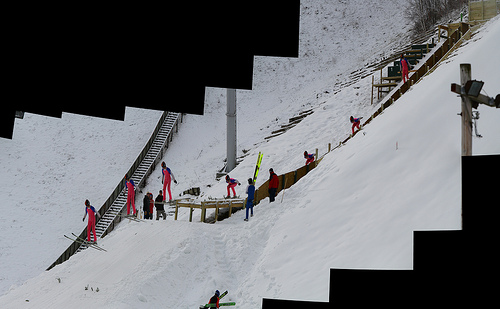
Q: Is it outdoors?
A: Yes, it is outdoors.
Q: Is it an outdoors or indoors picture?
A: It is outdoors.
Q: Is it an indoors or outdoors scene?
A: It is outdoors.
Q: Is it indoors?
A: No, it is outdoors.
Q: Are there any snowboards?
A: No, there are no snowboards.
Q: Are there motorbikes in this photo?
A: No, there are no motorbikes.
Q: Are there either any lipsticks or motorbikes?
A: No, there are no motorbikes or lipsticks.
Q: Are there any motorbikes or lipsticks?
A: No, there are no motorbikes or lipsticks.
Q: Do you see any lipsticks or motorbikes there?
A: No, there are no motorbikes or lipsticks.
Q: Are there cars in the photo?
A: No, there are no cars.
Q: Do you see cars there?
A: No, there are no cars.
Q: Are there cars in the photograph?
A: No, there are no cars.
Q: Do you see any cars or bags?
A: No, there are no cars or bags.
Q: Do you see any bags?
A: No, there are no bags.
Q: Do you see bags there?
A: No, there are no bags.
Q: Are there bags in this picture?
A: No, there are no bags.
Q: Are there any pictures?
A: No, there are no pictures.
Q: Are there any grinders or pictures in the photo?
A: No, there are no pictures or grinders.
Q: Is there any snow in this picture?
A: Yes, there is snow.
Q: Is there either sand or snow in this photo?
A: Yes, there is snow.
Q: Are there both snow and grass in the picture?
A: No, there is snow but no grass.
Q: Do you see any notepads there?
A: No, there are no notepads.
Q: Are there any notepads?
A: No, there are no notepads.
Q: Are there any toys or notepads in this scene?
A: No, there are no notepads or toys.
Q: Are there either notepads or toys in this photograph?
A: No, there are no notepads or toys.